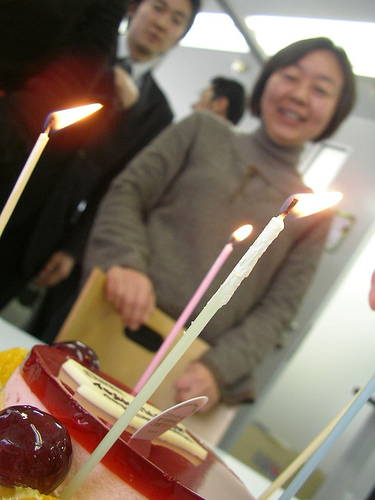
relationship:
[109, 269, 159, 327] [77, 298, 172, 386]
hand on chair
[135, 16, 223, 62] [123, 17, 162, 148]
head of man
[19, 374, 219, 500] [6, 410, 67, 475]
cake with cherry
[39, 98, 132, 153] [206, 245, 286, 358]
flame on candle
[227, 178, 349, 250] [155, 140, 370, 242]
candles has flames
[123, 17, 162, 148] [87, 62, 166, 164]
man in suit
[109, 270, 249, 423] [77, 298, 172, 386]
hands on chair